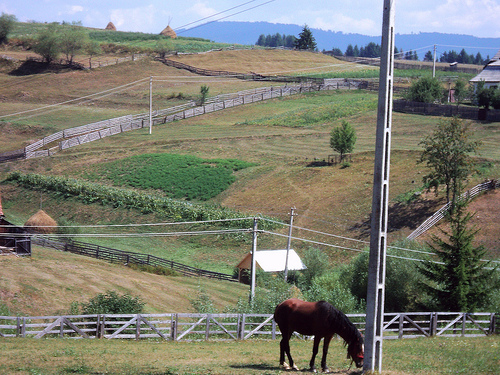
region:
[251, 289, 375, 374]
One horse in the shot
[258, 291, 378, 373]
This horse is brown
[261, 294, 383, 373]
Horse is looking downward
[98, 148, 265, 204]
Green is the color of the grass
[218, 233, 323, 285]
A small house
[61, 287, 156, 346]
A bush behind the fence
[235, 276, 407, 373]
Looking at a pole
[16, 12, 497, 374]
This is the country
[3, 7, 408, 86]
Wires on the pole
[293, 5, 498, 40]
Sky is full of clouds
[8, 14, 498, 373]
farmland in the country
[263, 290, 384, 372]
a horse in the grass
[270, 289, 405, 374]
a horse by a pole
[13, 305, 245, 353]
a fence in a field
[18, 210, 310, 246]
power lines on poles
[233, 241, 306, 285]
a building behind the poles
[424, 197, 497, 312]
an evergreen tree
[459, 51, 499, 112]
a building in the distance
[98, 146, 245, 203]
a patch of greenery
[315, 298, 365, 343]
a mane on a horse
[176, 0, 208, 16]
white clouds in blue sky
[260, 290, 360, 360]
brown horse grazing in field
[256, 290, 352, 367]
brown horse grazing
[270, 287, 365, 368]
brown horse in field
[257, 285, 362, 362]
brown horse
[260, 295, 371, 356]
horse grazing in field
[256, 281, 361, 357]
horse eating grass in field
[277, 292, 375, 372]
brown horse eating grass in field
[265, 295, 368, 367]
horse eating grass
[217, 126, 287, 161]
short green and brown grass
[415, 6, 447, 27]
white clouds in blue sky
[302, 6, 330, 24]
white clouds in blue sky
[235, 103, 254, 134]
short green and brown grass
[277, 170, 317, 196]
short green and brown grass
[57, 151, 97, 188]
short green and brown grass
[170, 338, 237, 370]
short green and brown grass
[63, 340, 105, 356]
short green and brown grass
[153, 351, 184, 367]
short green and brown grass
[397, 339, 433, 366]
short green and brown grass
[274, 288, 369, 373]
horse grazing by a pole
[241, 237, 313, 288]
a small barn with yellow roof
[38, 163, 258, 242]
green vegetation in an open field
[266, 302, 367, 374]
a brown horse with white hooves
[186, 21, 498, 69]
mountains in the distance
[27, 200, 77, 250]
a bale of hay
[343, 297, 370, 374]
white marking on horse's head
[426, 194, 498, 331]
a pine tree in the field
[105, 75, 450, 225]
open pasture for horses to graze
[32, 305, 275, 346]
corral fences to keep animals in